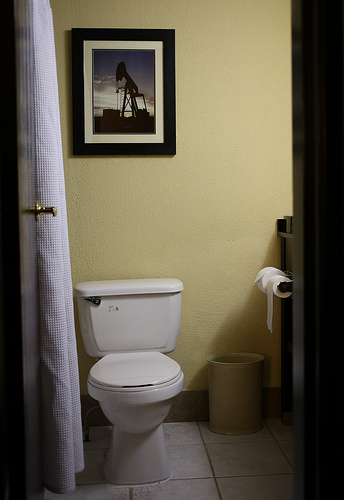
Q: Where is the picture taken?
A: A bathroom.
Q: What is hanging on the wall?
A: A picture.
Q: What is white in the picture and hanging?
A: Shower curtains.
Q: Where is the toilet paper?
A: The wall.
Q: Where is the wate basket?
A: Next to the toilet.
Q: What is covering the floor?
A: Tile.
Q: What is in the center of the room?
A: Toilet.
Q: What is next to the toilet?
A: A shower curtain.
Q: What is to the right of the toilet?
A: A trashcan.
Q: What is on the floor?
A: White tiles.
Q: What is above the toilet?
A: A framed picture.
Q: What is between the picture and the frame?
A: A white border.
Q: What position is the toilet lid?
A: Down.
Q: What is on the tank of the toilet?
A: A handle.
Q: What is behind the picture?
A: A wall.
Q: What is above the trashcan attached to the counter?
A: Toilet paper holder.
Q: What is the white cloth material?
A: A shower curtain.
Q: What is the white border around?
A: A picture.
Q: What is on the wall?
A: A picture.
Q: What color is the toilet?
A: White.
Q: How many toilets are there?
A: One.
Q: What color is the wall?
A: Yellow.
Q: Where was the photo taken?
A: In a bathroom.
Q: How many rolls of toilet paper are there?
A: Two.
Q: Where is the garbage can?
A: To the right of the toilet.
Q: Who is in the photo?
A: Nobody.